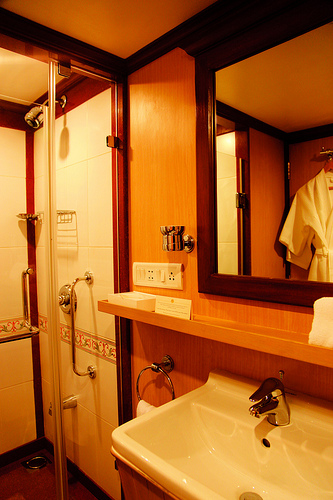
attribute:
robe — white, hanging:
[277, 168, 332, 284]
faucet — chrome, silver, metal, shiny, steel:
[246, 377, 291, 427]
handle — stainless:
[68, 270, 97, 380]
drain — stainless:
[26, 456, 47, 470]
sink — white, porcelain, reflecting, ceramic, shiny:
[111, 367, 332, 500]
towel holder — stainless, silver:
[135, 353, 176, 403]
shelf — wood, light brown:
[97, 297, 333, 369]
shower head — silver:
[23, 94, 68, 130]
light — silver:
[159, 225, 197, 254]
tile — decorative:
[0, 314, 118, 367]